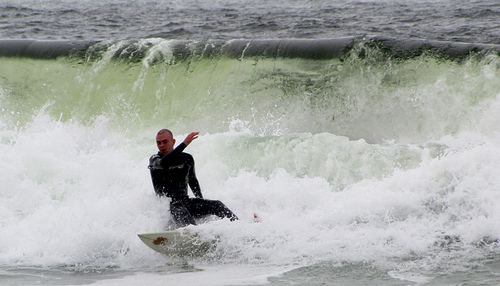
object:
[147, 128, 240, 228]
surfer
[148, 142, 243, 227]
suit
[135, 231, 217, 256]
surfboard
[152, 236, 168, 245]
logo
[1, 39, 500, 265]
wave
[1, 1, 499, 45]
water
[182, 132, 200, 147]
hand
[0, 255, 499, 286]
water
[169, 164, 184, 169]
logo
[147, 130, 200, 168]
arm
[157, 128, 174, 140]
hair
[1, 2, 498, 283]
ocean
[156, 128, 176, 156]
head